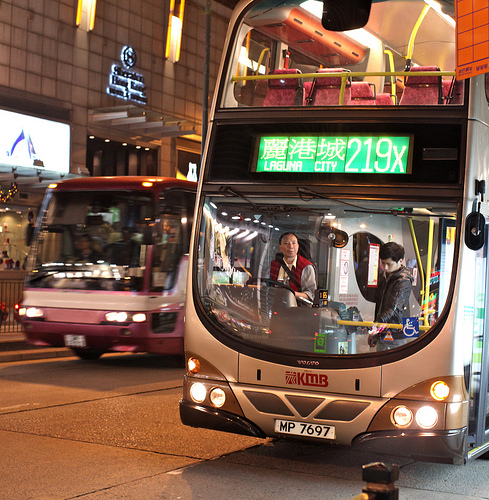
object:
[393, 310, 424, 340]
sticker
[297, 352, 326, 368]
medallion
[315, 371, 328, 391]
letters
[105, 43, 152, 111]
black sign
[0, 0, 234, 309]
building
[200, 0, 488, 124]
top level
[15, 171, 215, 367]
bus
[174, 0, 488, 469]
bus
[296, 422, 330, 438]
7697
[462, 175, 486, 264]
rearview mirror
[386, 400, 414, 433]
headlight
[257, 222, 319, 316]
bus driver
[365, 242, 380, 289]
paper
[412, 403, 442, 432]
light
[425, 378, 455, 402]
light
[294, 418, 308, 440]
number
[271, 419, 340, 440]
license plate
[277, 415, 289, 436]
black letter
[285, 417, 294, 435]
black letter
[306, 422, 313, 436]
black number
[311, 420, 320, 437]
black number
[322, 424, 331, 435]
black number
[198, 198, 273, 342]
reflection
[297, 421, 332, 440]
numbers 7697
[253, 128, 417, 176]
green light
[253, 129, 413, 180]
sign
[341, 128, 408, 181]
219x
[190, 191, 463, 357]
windshield